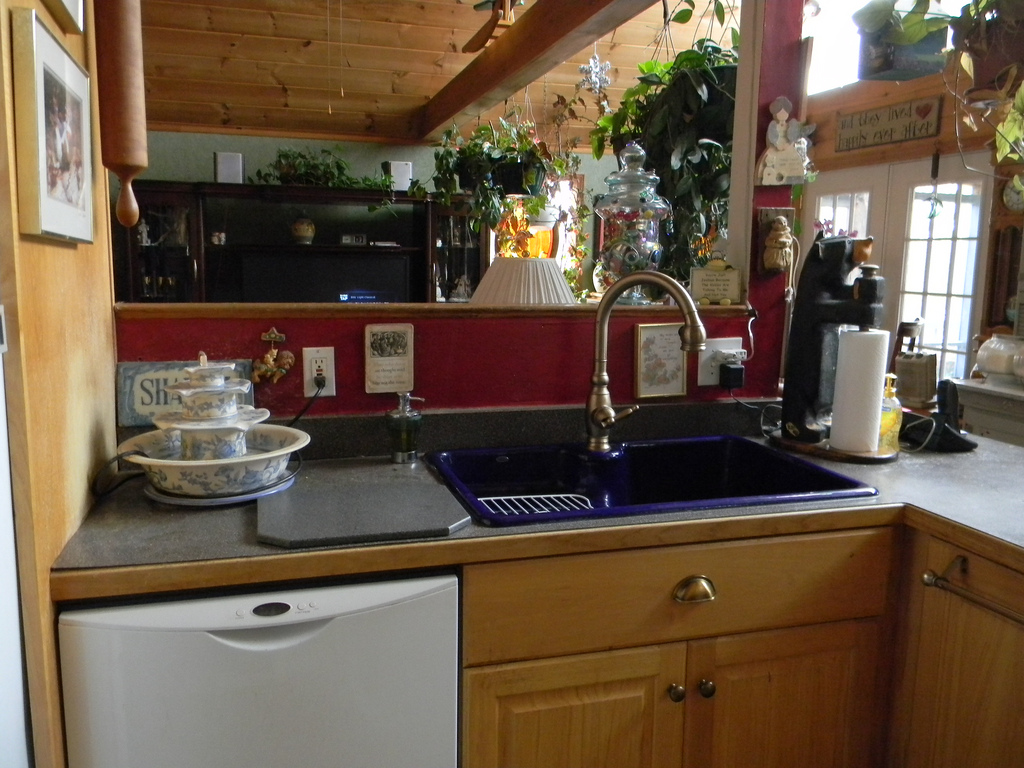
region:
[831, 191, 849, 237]
window pane on kitchen door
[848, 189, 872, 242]
window pane on kitchen door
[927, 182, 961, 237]
window pane on kitchen door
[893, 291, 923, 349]
window pane on kitchen door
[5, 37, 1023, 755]
Kitchen and family room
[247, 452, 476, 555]
Gray chopping board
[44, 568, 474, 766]
Clean white dishwasher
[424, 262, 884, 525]
Purple sink and faucet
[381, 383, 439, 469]
hand soap dispenser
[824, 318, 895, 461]
Roll of white paper towel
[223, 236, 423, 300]
Big black TV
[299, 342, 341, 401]
White power outlet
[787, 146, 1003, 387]
White french door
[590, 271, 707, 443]
a curved kitchen water faucet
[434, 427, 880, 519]
a blue kitchen sink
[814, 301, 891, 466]
paper towels on a holder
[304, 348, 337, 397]
the white face plate of a electrical socket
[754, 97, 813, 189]
a wooden decorative piece hanging on a post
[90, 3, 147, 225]
a wooden rolling pin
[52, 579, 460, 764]
the white door of a dishwasher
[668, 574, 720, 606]
a metal pull on a drawer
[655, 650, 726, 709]
metal knobs on cabinets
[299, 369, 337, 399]
a black plug in a socket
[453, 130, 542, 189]
the green potted plant hanging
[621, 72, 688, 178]
the green potted plant hanging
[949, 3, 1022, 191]
the green potted plant hanging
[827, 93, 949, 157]
the sign hanging on the wall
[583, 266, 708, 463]
the silver faucet of the sink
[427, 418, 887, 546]
the bright blue ceramic sink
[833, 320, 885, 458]
the roll of paper towels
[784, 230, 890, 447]
the wooden bear shaped paper towel holder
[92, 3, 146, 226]
the wooden rolling pin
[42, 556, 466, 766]
a white dish washer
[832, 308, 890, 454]
a roll of paper towels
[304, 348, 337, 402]
a white electrical outlet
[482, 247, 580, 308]
a white lamp shade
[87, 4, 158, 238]
a wood rolling pen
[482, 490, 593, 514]
a white metal rack in a sink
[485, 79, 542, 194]
a potted plant hanging from the ceiling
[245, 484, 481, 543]
a grey cutting board on a counter top